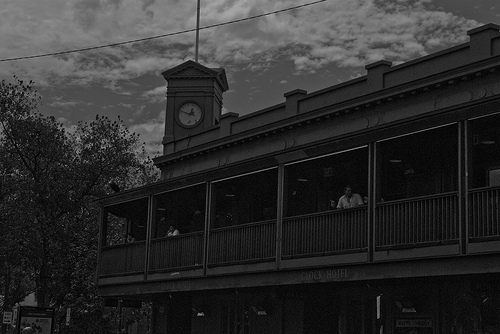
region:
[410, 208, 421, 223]
part of a rail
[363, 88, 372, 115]
part of a roof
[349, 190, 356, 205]
face of a man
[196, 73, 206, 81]
part of a castle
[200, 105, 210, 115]
tip of a house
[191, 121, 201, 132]
part of a clock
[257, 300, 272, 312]
part of a building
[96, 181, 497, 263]
balcony has a wooden fence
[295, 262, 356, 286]
hotel name is clock hotel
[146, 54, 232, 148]
tower has a clock on the front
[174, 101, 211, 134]
clock on tower is round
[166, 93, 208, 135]
time on clock is 1:50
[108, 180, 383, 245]
people are standing on the balcony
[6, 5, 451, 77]
many clouds are in the sky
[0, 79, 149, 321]
trees are next to the hotel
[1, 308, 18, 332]
street sign is next to a road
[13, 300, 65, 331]
advertisement is next to road sign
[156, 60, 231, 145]
tower has clock on it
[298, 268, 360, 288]
words on building say clock hotel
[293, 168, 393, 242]
people are standing on balcony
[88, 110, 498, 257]
balcony has multiple windows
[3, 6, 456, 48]
sky has many clouds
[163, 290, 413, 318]
lights are on side of building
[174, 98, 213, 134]
clock on tower says 1:50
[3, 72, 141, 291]
tree is on side of building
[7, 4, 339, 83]
wire is hanging over building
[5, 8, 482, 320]
photograph is brown in color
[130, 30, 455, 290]
wooden building with a clock tower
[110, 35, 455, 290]
wooden building with a clock tower and people watching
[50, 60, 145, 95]
clouds in the blue sky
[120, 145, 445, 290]
people looking over a wooden porch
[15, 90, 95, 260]
trees off in the distance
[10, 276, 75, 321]
name on a sign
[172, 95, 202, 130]
clock on the clock tower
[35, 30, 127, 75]
electric wire in the sky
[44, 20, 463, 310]
wooden building with a clock tower wiht people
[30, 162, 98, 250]
large green tree at the side of house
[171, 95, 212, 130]
clock at top of building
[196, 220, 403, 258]
long railing on porch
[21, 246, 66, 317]
trunk on tall tree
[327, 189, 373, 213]
man wearing long sleeve white shirt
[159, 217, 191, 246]
man leaning against railing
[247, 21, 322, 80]
rain clouds in the sky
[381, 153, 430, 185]
lights in the ceiling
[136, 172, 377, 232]
people standing on the balcony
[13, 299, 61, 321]
large sign on the ground